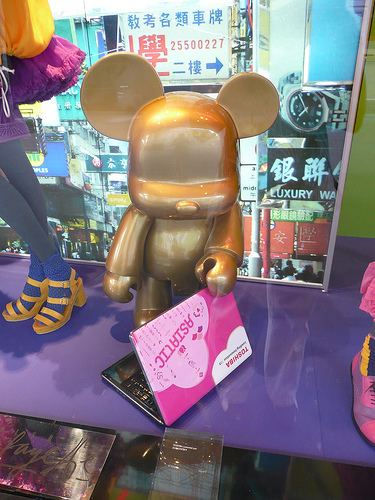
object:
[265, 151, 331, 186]
writing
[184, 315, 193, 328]
letter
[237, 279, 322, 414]
reflection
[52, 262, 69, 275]
pattern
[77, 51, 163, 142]
ear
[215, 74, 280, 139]
ear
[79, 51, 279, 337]
statue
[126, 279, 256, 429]
letter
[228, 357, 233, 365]
letter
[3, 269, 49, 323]
shoes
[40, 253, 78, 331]
blue socks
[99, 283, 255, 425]
laptop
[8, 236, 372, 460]
counter top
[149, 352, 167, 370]
letter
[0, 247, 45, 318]
socks